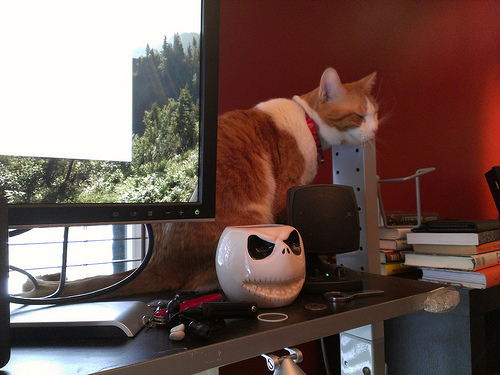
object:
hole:
[335, 150, 342, 159]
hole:
[352, 144, 362, 156]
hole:
[355, 164, 361, 171]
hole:
[354, 185, 363, 196]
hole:
[358, 221, 365, 233]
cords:
[7, 263, 40, 304]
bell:
[316, 156, 326, 165]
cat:
[22, 68, 382, 297]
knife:
[140, 283, 258, 340]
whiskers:
[373, 107, 393, 126]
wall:
[218, 0, 500, 218]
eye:
[353, 111, 365, 121]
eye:
[372, 106, 380, 115]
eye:
[282, 229, 301, 256]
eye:
[246, 233, 276, 259]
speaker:
[286, 182, 364, 295]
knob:
[343, 207, 353, 217]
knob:
[348, 225, 358, 237]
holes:
[334, 146, 367, 271]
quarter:
[304, 300, 328, 313]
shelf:
[2, 265, 453, 374]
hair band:
[256, 310, 287, 322]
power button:
[192, 209, 202, 218]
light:
[7, 225, 141, 294]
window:
[8, 224, 153, 304]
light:
[345, 206, 349, 216]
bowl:
[214, 223, 305, 311]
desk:
[0, 264, 452, 374]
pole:
[332, 145, 385, 374]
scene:
[0, 31, 203, 202]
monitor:
[2, 0, 204, 206]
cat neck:
[299, 96, 317, 110]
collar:
[303, 108, 325, 164]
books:
[403, 219, 500, 288]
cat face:
[328, 92, 380, 143]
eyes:
[345, 109, 380, 116]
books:
[378, 213, 500, 291]